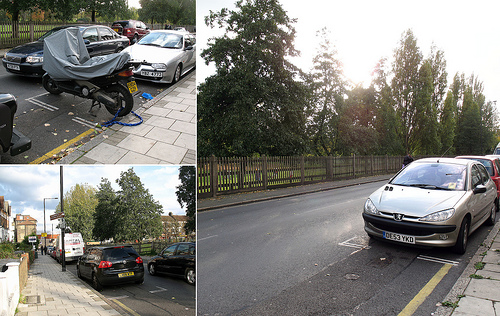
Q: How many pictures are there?
A: Three.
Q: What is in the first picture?
A: A bike and cars.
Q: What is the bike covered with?
A: With a plastic cover.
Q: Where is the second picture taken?
A: On the street.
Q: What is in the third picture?
A: A parked car.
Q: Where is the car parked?
A: By the street.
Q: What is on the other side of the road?
A: Trees and a fence.